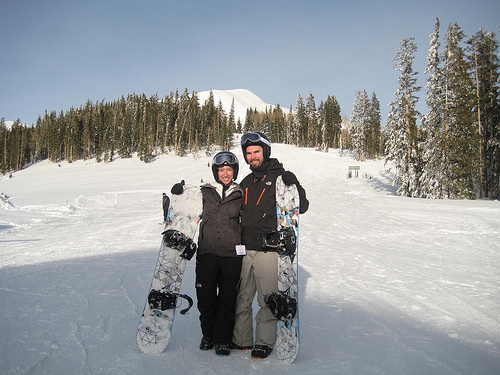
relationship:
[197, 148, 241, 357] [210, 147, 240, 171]
woman with googles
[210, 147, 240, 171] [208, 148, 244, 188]
googles on head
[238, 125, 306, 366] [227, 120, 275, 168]
man has a head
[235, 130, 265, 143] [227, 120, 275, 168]
goggles are on h head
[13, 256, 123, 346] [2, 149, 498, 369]
shadow on snow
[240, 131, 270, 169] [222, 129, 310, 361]
head of man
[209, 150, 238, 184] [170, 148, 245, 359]
head of woman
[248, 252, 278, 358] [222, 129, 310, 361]
leg of man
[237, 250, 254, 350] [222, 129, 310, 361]
leg of man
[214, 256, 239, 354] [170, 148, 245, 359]
leg of woman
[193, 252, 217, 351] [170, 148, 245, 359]
leg of woman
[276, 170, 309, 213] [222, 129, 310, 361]
arm of man